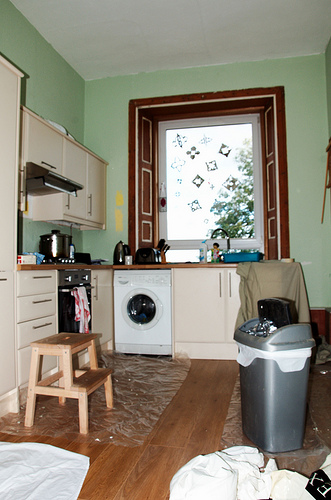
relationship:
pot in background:
[39, 230, 73, 258] [1, 1, 327, 300]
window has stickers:
[124, 94, 281, 255] [165, 133, 232, 204]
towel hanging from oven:
[70, 287, 95, 332] [54, 266, 97, 338]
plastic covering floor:
[2, 353, 193, 441] [204, 407, 242, 423]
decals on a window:
[190, 174, 205, 189] [195, 132, 255, 259]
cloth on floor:
[172, 453, 222, 486] [0, 341, 327, 499]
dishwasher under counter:
[113, 262, 173, 356] [17, 260, 301, 268]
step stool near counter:
[21, 326, 119, 431] [17, 253, 118, 352]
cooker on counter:
[38, 221, 72, 266] [19, 257, 124, 282]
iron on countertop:
[113, 240, 130, 267] [91, 258, 218, 275]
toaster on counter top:
[134, 247, 160, 263] [19, 261, 238, 268]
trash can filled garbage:
[227, 307, 319, 449] [238, 317, 273, 340]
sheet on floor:
[0, 440, 83, 498] [0, 306, 328, 497]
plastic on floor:
[2, 347, 193, 442] [0, 341, 327, 499]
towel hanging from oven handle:
[308, 136, 329, 242] [56, 278, 93, 299]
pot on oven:
[39, 230, 73, 258] [54, 266, 97, 338]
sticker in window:
[185, 146, 200, 159] [164, 122, 259, 262]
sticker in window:
[217, 142, 231, 157] [164, 122, 259, 262]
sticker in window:
[197, 133, 212, 146] [164, 122, 259, 262]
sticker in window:
[171, 132, 188, 148] [164, 122, 259, 262]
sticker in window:
[191, 174, 205, 188] [164, 122, 259, 262]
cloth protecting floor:
[172, 445, 307, 500] [0, 342, 331, 500]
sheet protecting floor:
[7, 445, 82, 491] [0, 342, 331, 500]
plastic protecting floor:
[2, 347, 193, 442] [0, 342, 331, 500]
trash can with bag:
[232, 297, 318, 453] [231, 337, 320, 379]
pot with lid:
[39, 230, 73, 258] [34, 229, 73, 237]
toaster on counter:
[134, 247, 160, 263] [108, 262, 244, 269]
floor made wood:
[184, 386, 214, 424] [85, 373, 219, 499]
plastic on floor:
[2, 347, 193, 442] [55, 346, 237, 456]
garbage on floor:
[246, 316, 276, 340] [122, 379, 239, 454]